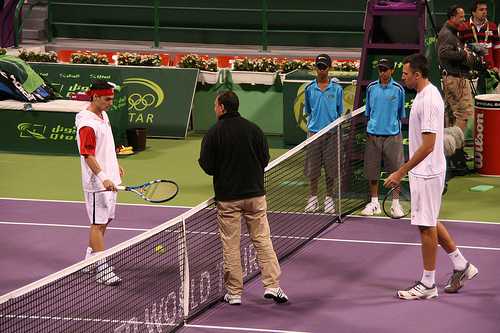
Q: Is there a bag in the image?
A: Yes, there is a bag.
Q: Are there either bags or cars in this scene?
A: Yes, there is a bag.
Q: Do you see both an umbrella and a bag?
A: No, there is a bag but no umbrellas.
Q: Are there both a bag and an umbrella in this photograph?
A: No, there is a bag but no umbrellas.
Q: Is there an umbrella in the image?
A: No, there are no umbrellas.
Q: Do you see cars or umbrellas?
A: No, there are no umbrellas or cars.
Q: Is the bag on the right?
A: No, the bag is on the left of the image.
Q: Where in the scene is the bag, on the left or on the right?
A: The bag is on the left of the image.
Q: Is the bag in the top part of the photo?
A: Yes, the bag is in the top of the image.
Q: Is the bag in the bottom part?
A: No, the bag is in the top of the image.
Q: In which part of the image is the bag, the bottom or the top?
A: The bag is in the top of the image.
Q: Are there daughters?
A: No, there are no daughters.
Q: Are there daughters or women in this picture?
A: No, there are no daughters or women.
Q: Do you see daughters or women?
A: No, there are no daughters or women.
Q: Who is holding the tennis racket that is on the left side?
A: The man is holding the racket.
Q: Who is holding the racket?
A: The man is holding the racket.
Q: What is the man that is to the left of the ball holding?
A: The man is holding the racket.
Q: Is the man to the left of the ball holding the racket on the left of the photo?
A: Yes, the man is holding the racket.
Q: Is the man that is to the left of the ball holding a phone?
A: No, the man is holding the racket.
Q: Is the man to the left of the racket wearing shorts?
A: Yes, the man is wearing shorts.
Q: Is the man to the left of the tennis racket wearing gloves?
A: No, the man is wearing shorts.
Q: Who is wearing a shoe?
A: The man is wearing a shoe.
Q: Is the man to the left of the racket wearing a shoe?
A: Yes, the man is wearing a shoe.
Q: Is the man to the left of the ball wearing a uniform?
A: No, the man is wearing a shoe.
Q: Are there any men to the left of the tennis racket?
A: Yes, there is a man to the left of the tennis racket.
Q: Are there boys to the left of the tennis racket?
A: No, there is a man to the left of the tennis racket.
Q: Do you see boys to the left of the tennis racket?
A: No, there is a man to the left of the tennis racket.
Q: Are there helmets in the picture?
A: No, there are no helmets.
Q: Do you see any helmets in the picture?
A: No, there are no helmets.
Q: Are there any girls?
A: No, there are no girls.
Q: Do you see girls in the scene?
A: No, there are no girls.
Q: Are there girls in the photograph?
A: No, there are no girls.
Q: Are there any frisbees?
A: No, there are no frisbees.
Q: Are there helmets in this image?
A: No, there are no helmets.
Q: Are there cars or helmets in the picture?
A: No, there are no helmets or cars.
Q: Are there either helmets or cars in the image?
A: No, there are no helmets or cars.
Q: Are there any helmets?
A: No, there are no helmets.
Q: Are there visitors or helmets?
A: No, there are no helmets or visitors.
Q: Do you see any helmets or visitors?
A: No, there are no helmets or visitors.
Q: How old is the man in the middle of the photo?
A: The man is young.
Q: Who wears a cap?
A: The man wears a cap.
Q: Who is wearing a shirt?
A: The man is wearing a shirt.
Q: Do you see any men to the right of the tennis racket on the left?
A: Yes, there is a man to the right of the racket.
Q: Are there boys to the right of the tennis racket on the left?
A: No, there is a man to the right of the tennis racket.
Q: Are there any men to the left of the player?
A: Yes, there is a man to the left of the player.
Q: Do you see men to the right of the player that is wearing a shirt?
A: No, the man is to the left of the player.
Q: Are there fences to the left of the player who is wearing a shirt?
A: No, there is a man to the left of the player.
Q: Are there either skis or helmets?
A: No, there are no skis or helmets.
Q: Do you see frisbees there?
A: No, there are no frisbees.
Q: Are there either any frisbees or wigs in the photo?
A: No, there are no frisbees or wigs.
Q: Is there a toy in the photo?
A: No, there are no toys.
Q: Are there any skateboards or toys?
A: No, there are no toys or skateboards.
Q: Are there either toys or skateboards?
A: No, there are no toys or skateboards.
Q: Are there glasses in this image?
A: No, there are no glasses.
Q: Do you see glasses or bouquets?
A: No, there are no glasses or bouquets.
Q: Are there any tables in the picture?
A: Yes, there is a table.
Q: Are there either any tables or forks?
A: Yes, there is a table.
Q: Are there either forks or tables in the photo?
A: Yes, there is a table.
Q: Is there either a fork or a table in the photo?
A: Yes, there is a table.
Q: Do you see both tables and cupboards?
A: No, there is a table but no cupboards.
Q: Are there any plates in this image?
A: No, there are no plates.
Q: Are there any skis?
A: No, there are no skis.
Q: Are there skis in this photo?
A: No, there are no skis.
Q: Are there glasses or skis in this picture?
A: No, there are no skis or glasses.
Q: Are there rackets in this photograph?
A: Yes, there is a racket.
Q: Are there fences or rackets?
A: Yes, there is a racket.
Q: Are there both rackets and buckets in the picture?
A: No, there is a racket but no buckets.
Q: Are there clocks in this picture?
A: No, there are no clocks.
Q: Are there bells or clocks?
A: No, there are no clocks or bells.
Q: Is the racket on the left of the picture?
A: Yes, the racket is on the left of the image.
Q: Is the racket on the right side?
A: No, the racket is on the left of the image.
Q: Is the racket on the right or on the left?
A: The racket is on the left of the image.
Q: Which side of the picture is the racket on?
A: The racket is on the left of the image.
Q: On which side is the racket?
A: The racket is on the left of the image.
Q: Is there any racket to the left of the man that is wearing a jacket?
A: Yes, there is a racket to the left of the man.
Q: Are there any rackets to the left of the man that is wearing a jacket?
A: Yes, there is a racket to the left of the man.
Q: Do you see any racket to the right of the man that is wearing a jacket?
A: No, the racket is to the left of the man.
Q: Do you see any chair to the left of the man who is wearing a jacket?
A: No, there is a racket to the left of the man.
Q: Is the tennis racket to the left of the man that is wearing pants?
A: Yes, the tennis racket is to the left of the man.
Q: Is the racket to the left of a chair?
A: No, the racket is to the left of the man.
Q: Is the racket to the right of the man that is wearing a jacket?
A: No, the racket is to the left of the man.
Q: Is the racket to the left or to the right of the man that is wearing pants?
A: The racket is to the left of the man.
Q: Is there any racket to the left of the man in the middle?
A: Yes, there is a racket to the left of the man.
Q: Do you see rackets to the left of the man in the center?
A: Yes, there is a racket to the left of the man.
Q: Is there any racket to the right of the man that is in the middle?
A: No, the racket is to the left of the man.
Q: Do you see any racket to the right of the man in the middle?
A: No, the racket is to the left of the man.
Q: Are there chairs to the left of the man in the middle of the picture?
A: No, there is a racket to the left of the man.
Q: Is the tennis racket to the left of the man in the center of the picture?
A: Yes, the tennis racket is to the left of the man.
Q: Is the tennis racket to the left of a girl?
A: No, the tennis racket is to the left of the man.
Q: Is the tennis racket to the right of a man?
A: No, the tennis racket is to the left of a man.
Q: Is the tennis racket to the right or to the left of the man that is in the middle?
A: The tennis racket is to the left of the man.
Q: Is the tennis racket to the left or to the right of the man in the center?
A: The tennis racket is to the left of the man.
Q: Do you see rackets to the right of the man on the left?
A: Yes, there is a racket to the right of the man.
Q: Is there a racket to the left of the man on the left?
A: No, the racket is to the right of the man.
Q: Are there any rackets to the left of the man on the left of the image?
A: No, the racket is to the right of the man.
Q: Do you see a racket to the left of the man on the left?
A: No, the racket is to the right of the man.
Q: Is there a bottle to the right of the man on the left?
A: No, there is a racket to the right of the man.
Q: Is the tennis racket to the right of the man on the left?
A: Yes, the tennis racket is to the right of the man.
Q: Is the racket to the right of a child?
A: No, the racket is to the right of the man.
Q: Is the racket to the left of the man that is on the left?
A: No, the racket is to the right of the man.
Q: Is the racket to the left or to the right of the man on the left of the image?
A: The racket is to the right of the man.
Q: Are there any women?
A: No, there are no women.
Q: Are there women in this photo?
A: No, there are no women.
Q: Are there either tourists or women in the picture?
A: No, there are no women or tourists.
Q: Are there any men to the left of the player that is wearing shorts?
A: Yes, there is a man to the left of the player.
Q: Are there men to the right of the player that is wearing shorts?
A: No, the man is to the left of the player.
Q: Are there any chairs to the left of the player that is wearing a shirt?
A: No, there is a man to the left of the player.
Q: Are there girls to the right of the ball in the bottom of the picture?
A: No, there is a man to the right of the ball.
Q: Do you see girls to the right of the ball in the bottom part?
A: No, there is a man to the right of the ball.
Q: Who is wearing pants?
A: The man is wearing pants.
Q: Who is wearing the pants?
A: The man is wearing pants.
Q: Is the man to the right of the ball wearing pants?
A: Yes, the man is wearing pants.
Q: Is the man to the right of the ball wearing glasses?
A: No, the man is wearing pants.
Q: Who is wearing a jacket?
A: The man is wearing a jacket.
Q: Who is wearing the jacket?
A: The man is wearing a jacket.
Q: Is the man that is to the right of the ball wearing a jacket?
A: Yes, the man is wearing a jacket.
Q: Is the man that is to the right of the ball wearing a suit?
A: No, the man is wearing a jacket.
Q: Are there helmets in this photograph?
A: No, there are no helmets.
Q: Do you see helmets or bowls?
A: No, there are no helmets or bowls.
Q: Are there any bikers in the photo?
A: No, there are no bikers.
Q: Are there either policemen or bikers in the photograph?
A: No, there are no bikers or policemen.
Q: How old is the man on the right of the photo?
A: The man is young.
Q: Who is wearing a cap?
A: The man is wearing a cap.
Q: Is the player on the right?
A: Yes, the player is on the right of the image.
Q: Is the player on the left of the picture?
A: No, the player is on the right of the image.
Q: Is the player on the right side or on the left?
A: The player is on the right of the image.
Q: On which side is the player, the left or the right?
A: The player is on the right of the image.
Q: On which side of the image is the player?
A: The player is on the right of the image.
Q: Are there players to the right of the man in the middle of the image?
A: Yes, there is a player to the right of the man.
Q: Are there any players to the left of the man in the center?
A: No, the player is to the right of the man.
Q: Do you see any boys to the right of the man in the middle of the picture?
A: No, there is a player to the right of the man.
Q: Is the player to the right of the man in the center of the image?
A: Yes, the player is to the right of the man.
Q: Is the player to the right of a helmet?
A: No, the player is to the right of the man.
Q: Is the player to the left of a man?
A: No, the player is to the right of a man.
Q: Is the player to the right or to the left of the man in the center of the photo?
A: The player is to the right of the man.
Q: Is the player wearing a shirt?
A: Yes, the player is wearing a shirt.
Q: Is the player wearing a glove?
A: No, the player is wearing a shirt.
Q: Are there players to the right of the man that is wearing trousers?
A: Yes, there is a player to the right of the man.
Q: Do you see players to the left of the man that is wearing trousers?
A: No, the player is to the right of the man.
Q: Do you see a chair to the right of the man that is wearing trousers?
A: No, there is a player to the right of the man.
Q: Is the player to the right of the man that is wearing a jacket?
A: Yes, the player is to the right of the man.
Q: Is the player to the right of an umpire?
A: No, the player is to the right of the man.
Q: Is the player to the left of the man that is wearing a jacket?
A: No, the player is to the right of the man.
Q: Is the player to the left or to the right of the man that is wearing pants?
A: The player is to the right of the man.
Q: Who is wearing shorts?
A: The player is wearing shorts.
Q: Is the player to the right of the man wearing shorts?
A: Yes, the player is wearing shorts.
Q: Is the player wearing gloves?
A: No, the player is wearing shorts.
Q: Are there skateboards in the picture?
A: No, there are no skateboards.